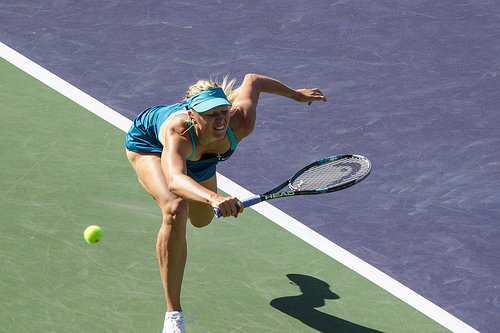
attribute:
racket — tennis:
[212, 150, 372, 217]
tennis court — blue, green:
[3, 2, 497, 331]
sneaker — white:
[158, 304, 186, 331]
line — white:
[1, 40, 480, 331]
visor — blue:
[172, 77, 240, 115]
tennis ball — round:
[82, 222, 102, 244]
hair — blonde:
[182, 65, 235, 97]